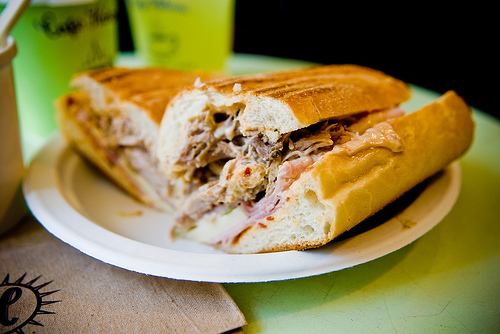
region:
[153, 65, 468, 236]
a half of a sandwich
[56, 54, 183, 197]
a half of a sandwich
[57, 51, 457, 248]
a whole sandwich cut in half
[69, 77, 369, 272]
a sandwich on a plate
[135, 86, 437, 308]
a white plate with a sandwich on it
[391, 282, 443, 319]
a green table top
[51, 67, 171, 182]
a hoagie sandwich on a plate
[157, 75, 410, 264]
a hoagie sandwich on a plate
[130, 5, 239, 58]
a green cup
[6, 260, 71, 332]
a brown napkin with a a design on it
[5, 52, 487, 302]
sandwich on a plate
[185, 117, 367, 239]
meat in the sandwich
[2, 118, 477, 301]
the plate is paper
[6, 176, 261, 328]
a napkin under the plate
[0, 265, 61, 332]
a design on the napkin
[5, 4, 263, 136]
cups behind the plate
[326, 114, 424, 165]
sauce on the bread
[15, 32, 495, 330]
the tablecloth is green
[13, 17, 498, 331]
the plate is on a table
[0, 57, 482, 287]
the plate is round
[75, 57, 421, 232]
sandwich on the plate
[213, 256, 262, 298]
edge of white plate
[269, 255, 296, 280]
edge of white plate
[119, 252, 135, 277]
edge of white plate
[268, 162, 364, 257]
toasted bread of sandwich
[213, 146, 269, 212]
meat inside of sandwich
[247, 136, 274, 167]
meat inside of sandwich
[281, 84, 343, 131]
toasted bread on top of sandwich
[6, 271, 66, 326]
logo on top of napkin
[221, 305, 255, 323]
corner of brown napkin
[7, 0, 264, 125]
two cups of beverage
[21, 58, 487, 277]
sandwich on plate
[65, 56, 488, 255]
bun of the sandwich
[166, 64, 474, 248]
foreground slice of sandwich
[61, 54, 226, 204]
background slice of sandwich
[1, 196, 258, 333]
brown napkin with logo on it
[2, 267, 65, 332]
black logo on napkin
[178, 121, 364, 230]
chunks of meat in sandwich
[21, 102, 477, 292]
white plate sandwich is on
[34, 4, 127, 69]
black writing on beverage cup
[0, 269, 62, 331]
Star shaped logo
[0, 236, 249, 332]
Brownish-white table mat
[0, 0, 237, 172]
Couple of greenish plastic containers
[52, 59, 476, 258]
Two large pieces of pie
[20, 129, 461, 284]
Wide, white and flat plate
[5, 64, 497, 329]
Green colored table top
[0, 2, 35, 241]
Part of a laddle and jar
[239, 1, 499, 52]
Shade of pitch black color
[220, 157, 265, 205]
Meat piece in a pie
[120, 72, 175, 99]
Patch of brown color